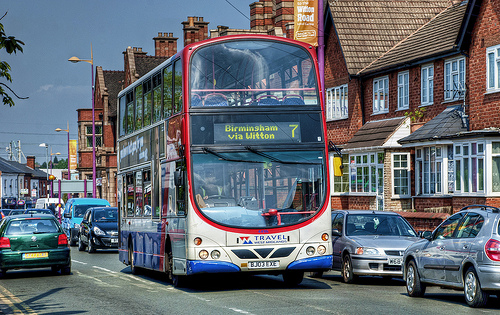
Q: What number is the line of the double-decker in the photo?
A: 7.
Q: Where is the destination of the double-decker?
A: Birmingham.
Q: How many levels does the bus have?
A: Two.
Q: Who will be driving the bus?
A: A bus driver.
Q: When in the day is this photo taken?
A: Daytime.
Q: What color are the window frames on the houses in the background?
A: White.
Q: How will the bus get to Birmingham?
A: Via Witton.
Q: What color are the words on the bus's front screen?
A: Green.